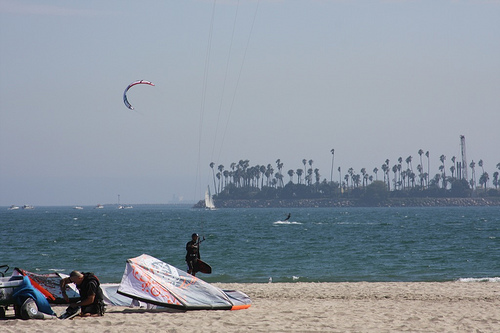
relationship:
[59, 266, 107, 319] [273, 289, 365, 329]
man sitting on sand